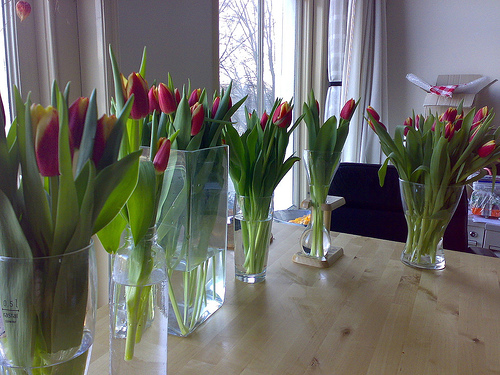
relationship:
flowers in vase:
[152, 135, 172, 174] [137, 140, 228, 327]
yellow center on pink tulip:
[32, 107, 52, 134] [38, 132, 71, 169]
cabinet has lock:
[456, 174, 498, 252] [464, 228, 479, 240]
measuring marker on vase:
[2, 296, 24, 326] [0, 238, 102, 374]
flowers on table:
[152, 135, 172, 174] [87, 221, 499, 373]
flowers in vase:
[152, 135, 172, 174] [0, 238, 102, 374]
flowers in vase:
[366, 97, 498, 260] [396, 177, 466, 271]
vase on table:
[396, 177, 466, 271] [2, 217, 499, 374]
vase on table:
[0, 238, 102, 374] [2, 217, 499, 374]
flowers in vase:
[152, 135, 172, 174] [109, 225, 170, 374]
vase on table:
[109, 225, 170, 374] [87, 221, 499, 373]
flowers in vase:
[0, 92, 142, 258] [0, 238, 102, 374]